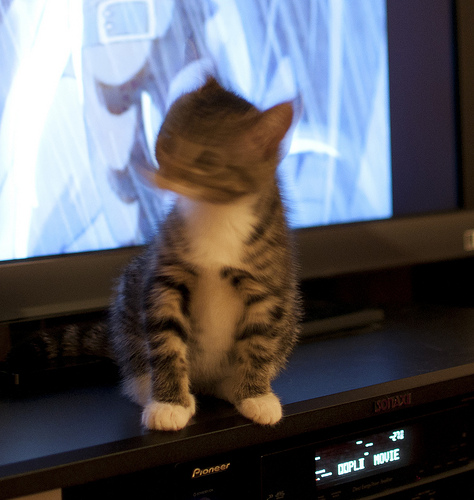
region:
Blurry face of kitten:
[148, 71, 309, 221]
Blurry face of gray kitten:
[137, 60, 314, 215]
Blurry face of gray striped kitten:
[135, 64, 301, 233]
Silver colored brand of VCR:
[169, 450, 242, 489]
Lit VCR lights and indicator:
[296, 428, 440, 490]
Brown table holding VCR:
[321, 302, 469, 396]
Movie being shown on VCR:
[20, 8, 393, 91]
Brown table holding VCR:
[15, 375, 136, 477]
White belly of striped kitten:
[186, 216, 247, 389]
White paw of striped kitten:
[232, 379, 291, 439]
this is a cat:
[120, 75, 281, 422]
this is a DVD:
[216, 437, 421, 475]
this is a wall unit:
[317, 336, 436, 377]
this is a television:
[324, 33, 464, 249]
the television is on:
[24, 7, 387, 75]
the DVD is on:
[297, 434, 414, 479]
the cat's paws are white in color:
[141, 396, 277, 429]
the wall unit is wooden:
[368, 337, 418, 372]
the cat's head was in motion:
[161, 75, 270, 200]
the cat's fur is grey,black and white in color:
[155, 314, 278, 386]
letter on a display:
[324, 446, 412, 472]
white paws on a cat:
[130, 405, 288, 430]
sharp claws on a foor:
[251, 409, 276, 426]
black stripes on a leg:
[146, 282, 194, 373]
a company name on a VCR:
[187, 458, 270, 479]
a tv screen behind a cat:
[25, 11, 430, 231]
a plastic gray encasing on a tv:
[363, 211, 455, 265]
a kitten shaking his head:
[93, 77, 335, 441]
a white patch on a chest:
[196, 219, 229, 322]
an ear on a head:
[228, 93, 328, 166]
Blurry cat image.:
[110, 93, 252, 367]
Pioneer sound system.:
[170, 453, 245, 480]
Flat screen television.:
[20, 173, 116, 300]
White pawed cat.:
[141, 368, 296, 467]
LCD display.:
[286, 420, 426, 491]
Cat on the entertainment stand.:
[108, 150, 324, 419]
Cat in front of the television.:
[102, 161, 317, 485]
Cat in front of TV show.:
[67, 74, 367, 359]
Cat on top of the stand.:
[89, 63, 327, 469]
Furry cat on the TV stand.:
[125, 255, 334, 451]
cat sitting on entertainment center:
[111, 77, 295, 426]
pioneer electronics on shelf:
[103, 411, 426, 489]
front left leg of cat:
[238, 271, 289, 424]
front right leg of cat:
[144, 267, 194, 429]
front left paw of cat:
[238, 391, 288, 424]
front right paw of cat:
[141, 397, 187, 436]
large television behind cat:
[1, 0, 472, 323]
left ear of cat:
[254, 95, 290, 162]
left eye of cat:
[194, 145, 223, 170]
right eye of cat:
[156, 126, 180, 155]